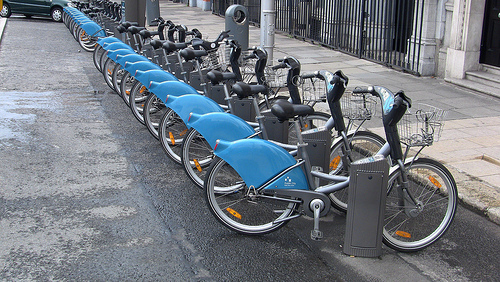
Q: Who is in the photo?
A: No one.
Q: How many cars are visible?
A: One.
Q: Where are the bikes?
A: Parked in a row.